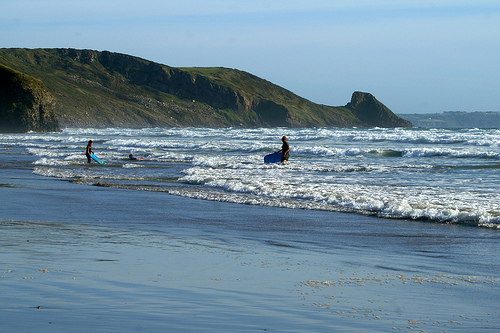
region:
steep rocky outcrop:
[5, 48, 406, 135]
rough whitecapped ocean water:
[0, 128, 499, 231]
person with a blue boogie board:
[259, 133, 296, 168]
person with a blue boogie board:
[85, 135, 100, 170]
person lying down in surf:
[127, 150, 143, 162]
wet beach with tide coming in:
[0, 225, 499, 332]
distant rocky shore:
[407, 110, 498, 132]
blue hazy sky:
[3, 0, 498, 107]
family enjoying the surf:
[77, 133, 311, 175]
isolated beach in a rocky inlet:
[5, 3, 499, 331]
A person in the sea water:
[280, 131, 290, 156]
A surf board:
[260, 145, 280, 160]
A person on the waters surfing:
[120, 140, 151, 165]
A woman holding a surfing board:
[75, 130, 100, 165]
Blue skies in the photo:
[236, 18, 316, 53]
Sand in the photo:
[111, 265, 258, 310]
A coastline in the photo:
[206, 185, 478, 290]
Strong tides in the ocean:
[276, 170, 383, 208]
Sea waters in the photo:
[407, 151, 467, 178]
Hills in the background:
[74, 45, 236, 113]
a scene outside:
[1, 0, 498, 323]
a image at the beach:
[1, 0, 496, 331]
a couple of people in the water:
[61, 124, 306, 184]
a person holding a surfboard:
[255, 128, 301, 176]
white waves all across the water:
[0, 113, 497, 256]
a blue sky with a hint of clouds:
[0, 1, 497, 119]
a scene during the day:
[2, 3, 497, 330]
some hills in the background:
[1, 35, 416, 152]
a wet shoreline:
[5, 197, 499, 332]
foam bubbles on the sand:
[288, 271, 496, 328]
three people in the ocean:
[82, 130, 289, 167]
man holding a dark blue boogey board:
[262, 133, 292, 168]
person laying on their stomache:
[122, 152, 144, 164]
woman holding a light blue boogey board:
[83, 139, 104, 165]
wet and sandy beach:
[0, 140, 497, 331]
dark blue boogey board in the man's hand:
[263, 149, 282, 164]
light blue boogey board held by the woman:
[88, 152, 104, 165]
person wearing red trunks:
[123, 151, 148, 166]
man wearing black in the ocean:
[276, 135, 291, 166]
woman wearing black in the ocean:
[82, 139, 95, 163]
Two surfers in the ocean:
[69, 111, 311, 186]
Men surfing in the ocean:
[55, 115, 323, 214]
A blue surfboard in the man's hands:
[259, 146, 291, 172]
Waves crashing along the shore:
[112, 168, 487, 237]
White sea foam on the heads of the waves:
[334, 190, 491, 218]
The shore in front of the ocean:
[14, 221, 448, 328]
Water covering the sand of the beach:
[20, 217, 406, 331]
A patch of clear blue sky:
[292, 15, 461, 84]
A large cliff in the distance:
[18, 42, 419, 137]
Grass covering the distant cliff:
[193, 62, 290, 102]